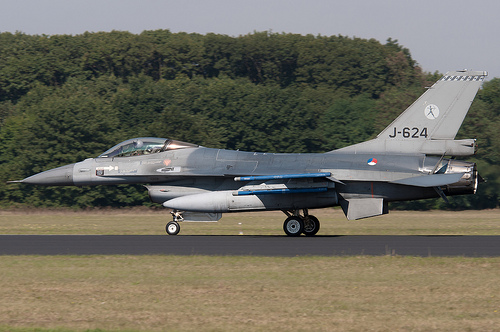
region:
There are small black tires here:
[288, 215, 302, 275]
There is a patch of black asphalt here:
[332, 234, 340, 260]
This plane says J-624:
[389, 120, 431, 146]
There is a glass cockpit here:
[116, 137, 163, 172]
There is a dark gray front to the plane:
[17, 169, 40, 209]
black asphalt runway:
[0, 232, 498, 257]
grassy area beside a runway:
[2, 254, 498, 331]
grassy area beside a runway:
[1, 207, 498, 234]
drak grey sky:
[0, 0, 498, 82]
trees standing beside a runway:
[0, 29, 498, 212]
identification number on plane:
[386, 124, 428, 139]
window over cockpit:
[97, 136, 200, 159]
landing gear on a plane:
[163, 206, 320, 236]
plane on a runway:
[6, 70, 488, 232]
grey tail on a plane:
[328, 71, 483, 153]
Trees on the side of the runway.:
[26, 39, 366, 151]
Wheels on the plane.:
[265, 201, 345, 240]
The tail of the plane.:
[393, 62, 480, 145]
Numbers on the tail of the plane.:
[384, 121, 439, 146]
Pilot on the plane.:
[124, 134, 149, 151]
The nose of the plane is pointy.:
[8, 152, 66, 188]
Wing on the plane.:
[233, 167, 326, 200]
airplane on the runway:
[11, 53, 496, 238]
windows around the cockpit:
[95, 130, 182, 162]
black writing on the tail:
[382, 124, 432, 139]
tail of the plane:
[359, 51, 494, 222]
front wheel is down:
[161, 210, 188, 234]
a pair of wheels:
[278, 211, 332, 238]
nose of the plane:
[9, 132, 81, 212]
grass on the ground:
[0, 253, 497, 330]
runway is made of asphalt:
[1, 229, 499, 256]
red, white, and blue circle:
[363, 154, 382, 169]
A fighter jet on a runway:
[5, 60, 490, 241]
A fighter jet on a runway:
[2, 66, 497, 241]